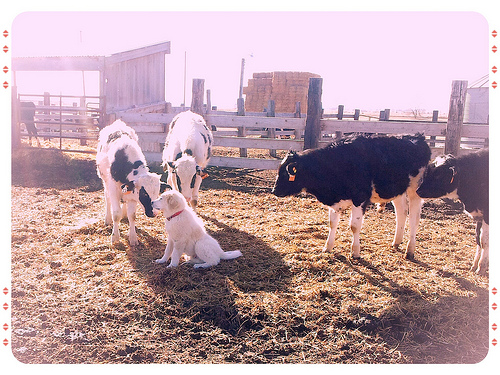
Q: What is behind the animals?
A: A fence.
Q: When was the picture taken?
A: Daytime.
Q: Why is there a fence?
A: To control the animals.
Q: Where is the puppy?
A: Near the goats.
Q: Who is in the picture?
A: Nobody.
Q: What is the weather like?
A: Sunny.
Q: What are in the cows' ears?
A: Tags.